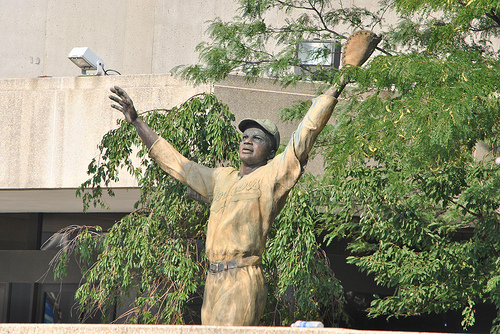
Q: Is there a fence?
A: No, there are no fences.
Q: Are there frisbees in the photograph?
A: No, there are no frisbees.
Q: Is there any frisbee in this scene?
A: No, there are no frisbees.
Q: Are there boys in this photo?
A: No, there are no boys.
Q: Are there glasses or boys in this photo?
A: No, there are no boys or glasses.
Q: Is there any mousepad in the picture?
A: No, there are no mouse pads.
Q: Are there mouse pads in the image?
A: No, there are no mouse pads.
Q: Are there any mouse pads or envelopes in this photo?
A: No, there are no mouse pads or envelopes.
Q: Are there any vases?
A: No, there are no vases.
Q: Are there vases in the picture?
A: No, there are no vases.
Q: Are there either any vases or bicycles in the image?
A: No, there are no vases or bicycles.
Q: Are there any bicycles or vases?
A: No, there are no vases or bicycles.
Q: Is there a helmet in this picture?
A: No, there are no helmets.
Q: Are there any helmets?
A: No, there are no helmets.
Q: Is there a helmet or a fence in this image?
A: No, there are no helmets or fences.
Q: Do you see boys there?
A: No, there are no boys.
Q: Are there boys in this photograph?
A: No, there are no boys.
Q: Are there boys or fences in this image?
A: No, there are no boys or fences.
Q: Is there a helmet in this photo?
A: No, there are no helmets.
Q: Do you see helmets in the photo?
A: No, there are no helmets.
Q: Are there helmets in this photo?
A: No, there are no helmets.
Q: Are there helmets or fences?
A: No, there are no helmets or fences.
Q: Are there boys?
A: No, there are no boys.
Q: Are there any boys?
A: No, there are no boys.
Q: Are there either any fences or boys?
A: No, there are no boys or fences.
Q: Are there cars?
A: No, there are no cars.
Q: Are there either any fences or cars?
A: No, there are no cars or fences.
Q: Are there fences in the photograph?
A: No, there are no fences.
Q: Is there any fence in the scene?
A: No, there are no fences.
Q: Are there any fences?
A: No, there are no fences.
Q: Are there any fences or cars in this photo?
A: No, there are no fences or cars.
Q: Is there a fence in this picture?
A: No, there are no fences.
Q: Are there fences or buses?
A: No, there are no fences or buses.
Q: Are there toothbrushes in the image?
A: No, there are no toothbrushes.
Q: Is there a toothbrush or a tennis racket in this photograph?
A: No, there are no toothbrushes or rackets.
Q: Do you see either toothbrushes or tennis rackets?
A: No, there are no toothbrushes or tennis rackets.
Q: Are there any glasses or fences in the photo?
A: No, there are no fences or glasses.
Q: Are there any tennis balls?
A: No, there are no tennis balls.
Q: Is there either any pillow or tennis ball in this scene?
A: No, there are no tennis balls or pillows.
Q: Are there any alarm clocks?
A: No, there are no alarm clocks.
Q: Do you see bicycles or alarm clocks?
A: No, there are no alarm clocks or bicycles.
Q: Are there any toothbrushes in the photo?
A: No, there are no toothbrushes.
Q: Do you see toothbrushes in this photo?
A: No, there are no toothbrushes.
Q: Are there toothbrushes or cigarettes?
A: No, there are no toothbrushes or cigarettes.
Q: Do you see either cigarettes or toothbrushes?
A: No, there are no toothbrushes or cigarettes.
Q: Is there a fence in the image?
A: No, there are no fences.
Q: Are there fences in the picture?
A: No, there are no fences.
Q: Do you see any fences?
A: No, there are no fences.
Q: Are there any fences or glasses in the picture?
A: No, there are no fences or glasses.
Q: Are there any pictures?
A: No, there are no pictures.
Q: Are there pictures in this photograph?
A: No, there are no pictures.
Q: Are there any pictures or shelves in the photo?
A: No, there are no pictures or shelves.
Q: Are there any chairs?
A: No, there are no chairs.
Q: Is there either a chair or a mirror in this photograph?
A: No, there are no chairs or mirrors.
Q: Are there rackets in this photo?
A: No, there are no rackets.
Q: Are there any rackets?
A: No, there are no rackets.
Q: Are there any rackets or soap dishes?
A: No, there are no rackets or soap dishes.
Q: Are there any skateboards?
A: No, there are no skateboards.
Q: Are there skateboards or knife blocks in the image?
A: No, there are no skateboards or knife blocks.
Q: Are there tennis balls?
A: No, there are no tennis balls.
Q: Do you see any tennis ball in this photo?
A: No, there are no tennis balls.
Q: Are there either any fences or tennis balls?
A: No, there are no tennis balls or fences.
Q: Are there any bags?
A: No, there are no bags.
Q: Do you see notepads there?
A: No, there are no notepads.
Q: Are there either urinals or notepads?
A: No, there are no notepads or urinals.